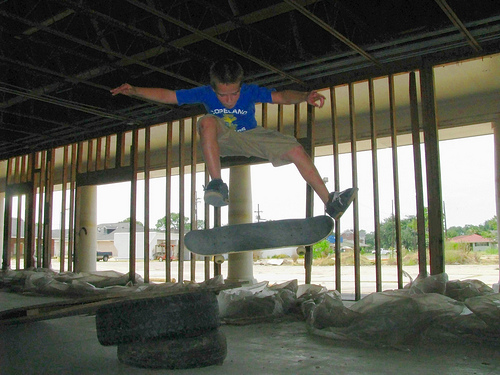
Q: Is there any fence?
A: No, there are no fences.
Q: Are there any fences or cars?
A: No, there are no fences or cars.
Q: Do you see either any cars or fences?
A: No, there are no fences or cars.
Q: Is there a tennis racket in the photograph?
A: No, there are no rackets.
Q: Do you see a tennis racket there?
A: No, there are no rackets.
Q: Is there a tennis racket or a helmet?
A: No, there are no rackets or helmets.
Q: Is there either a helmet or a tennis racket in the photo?
A: No, there are no rackets or helmets.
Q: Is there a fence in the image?
A: No, there are no fences.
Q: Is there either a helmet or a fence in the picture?
A: No, there are no fences or helmets.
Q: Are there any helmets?
A: No, there are no helmets.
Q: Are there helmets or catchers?
A: No, there are no helmets or catchers.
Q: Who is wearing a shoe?
A: The boy is wearing a shoe.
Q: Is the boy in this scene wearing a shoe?
A: Yes, the boy is wearing a shoe.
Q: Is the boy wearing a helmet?
A: No, the boy is wearing a shoe.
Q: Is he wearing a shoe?
A: Yes, the boy is wearing a shoe.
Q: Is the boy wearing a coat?
A: No, the boy is wearing a shoe.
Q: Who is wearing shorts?
A: The boy is wearing shorts.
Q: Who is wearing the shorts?
A: The boy is wearing shorts.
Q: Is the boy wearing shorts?
A: Yes, the boy is wearing shorts.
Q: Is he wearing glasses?
A: No, the boy is wearing shorts.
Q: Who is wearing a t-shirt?
A: The boy is wearing a t-shirt.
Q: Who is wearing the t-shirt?
A: The boy is wearing a t-shirt.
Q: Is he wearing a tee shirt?
A: Yes, the boy is wearing a tee shirt.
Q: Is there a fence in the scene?
A: No, there are no fences.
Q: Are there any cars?
A: No, there are no cars.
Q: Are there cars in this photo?
A: No, there are no cars.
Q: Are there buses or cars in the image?
A: No, there are no cars or buses.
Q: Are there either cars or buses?
A: No, there are no cars or buses.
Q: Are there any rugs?
A: No, there are no rugs.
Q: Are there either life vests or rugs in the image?
A: No, there are no rugs or life vests.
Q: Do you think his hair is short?
A: Yes, the hair is short.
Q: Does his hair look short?
A: Yes, the hair is short.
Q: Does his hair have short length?
A: Yes, the hair is short.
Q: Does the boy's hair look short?
A: Yes, the hair is short.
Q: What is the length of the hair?
A: The hair is short.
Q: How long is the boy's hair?
A: The hair is short.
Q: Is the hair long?
A: No, the hair is short.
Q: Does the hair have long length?
A: No, the hair is short.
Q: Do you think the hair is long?
A: No, the hair is short.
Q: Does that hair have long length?
A: No, the hair is short.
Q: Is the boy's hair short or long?
A: The hair is short.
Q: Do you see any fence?
A: No, there are no fences.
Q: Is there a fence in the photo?
A: No, there are no fences.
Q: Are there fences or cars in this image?
A: No, there are no fences or cars.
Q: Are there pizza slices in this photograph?
A: No, there are no pizza slices.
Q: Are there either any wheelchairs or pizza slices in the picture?
A: No, there are no pizza slices or wheelchairs.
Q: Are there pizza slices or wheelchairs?
A: No, there are no pizza slices or wheelchairs.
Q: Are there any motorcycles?
A: No, there are no motorcycles.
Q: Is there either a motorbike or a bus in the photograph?
A: No, there are no motorcycles or buses.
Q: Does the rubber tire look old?
A: Yes, the tire is old.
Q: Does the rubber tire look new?
A: No, the tire is old.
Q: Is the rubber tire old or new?
A: The tire is old.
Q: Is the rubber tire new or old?
A: The tire is old.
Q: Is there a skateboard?
A: Yes, there is a skateboard.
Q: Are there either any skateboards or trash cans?
A: Yes, there is a skateboard.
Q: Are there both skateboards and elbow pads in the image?
A: No, there is a skateboard but no elbow pads.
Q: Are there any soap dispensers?
A: No, there are no soap dispensers.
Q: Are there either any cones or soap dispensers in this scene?
A: No, there are no soap dispensers or cones.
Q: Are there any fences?
A: No, there are no fences.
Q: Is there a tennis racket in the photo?
A: No, there are no rackets.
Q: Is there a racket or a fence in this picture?
A: No, there are no rackets or fences.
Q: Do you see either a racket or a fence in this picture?
A: No, there are no rackets or fences.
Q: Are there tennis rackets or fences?
A: No, there are no tennis rackets or fences.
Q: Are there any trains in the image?
A: No, there are no trains.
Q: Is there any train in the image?
A: No, there are no trains.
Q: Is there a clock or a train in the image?
A: No, there are no trains or clocks.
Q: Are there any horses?
A: Yes, there is a horse.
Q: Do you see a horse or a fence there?
A: Yes, there is a horse.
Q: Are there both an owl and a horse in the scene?
A: No, there is a horse but no owls.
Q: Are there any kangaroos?
A: No, there are no kangaroos.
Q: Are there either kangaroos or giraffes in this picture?
A: No, there are no kangaroos or giraffes.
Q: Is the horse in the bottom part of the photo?
A: No, the horse is in the top of the image.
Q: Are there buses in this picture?
A: No, there are no buses.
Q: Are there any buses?
A: No, there are no buses.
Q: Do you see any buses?
A: No, there are no buses.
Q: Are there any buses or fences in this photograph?
A: No, there are no buses or fences.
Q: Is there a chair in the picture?
A: No, there are no chairs.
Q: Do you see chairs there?
A: No, there are no chairs.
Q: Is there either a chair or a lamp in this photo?
A: No, there are no chairs or lamps.